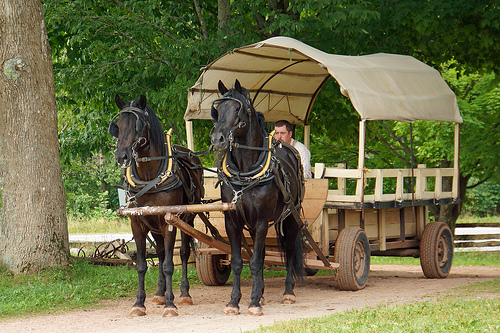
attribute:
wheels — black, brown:
[328, 214, 468, 294]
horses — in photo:
[67, 82, 344, 330]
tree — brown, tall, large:
[1, 0, 76, 272]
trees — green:
[134, 9, 445, 47]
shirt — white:
[289, 137, 311, 178]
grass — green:
[263, 280, 498, 332]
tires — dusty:
[192, 219, 469, 286]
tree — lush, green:
[391, 56, 498, 204]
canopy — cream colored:
[184, 35, 461, 123]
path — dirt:
[6, 261, 497, 327]